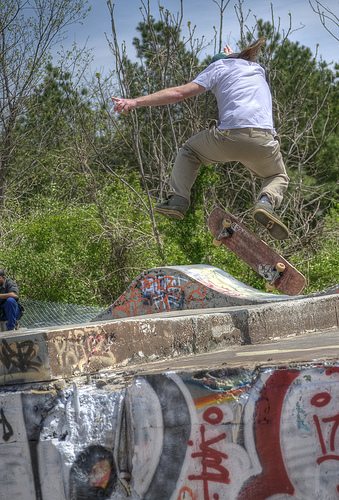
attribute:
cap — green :
[206, 43, 228, 65]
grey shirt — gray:
[209, 62, 264, 112]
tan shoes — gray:
[156, 191, 200, 230]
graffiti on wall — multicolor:
[133, 365, 337, 500]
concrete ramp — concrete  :
[5, 299, 331, 373]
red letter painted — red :
[170, 367, 337, 499]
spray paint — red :
[5, 379, 192, 494]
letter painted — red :
[203, 400, 230, 427]